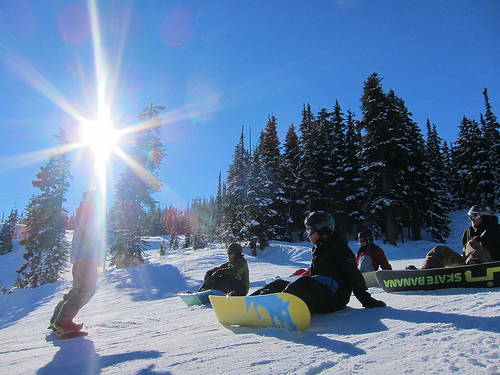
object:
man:
[247, 210, 386, 313]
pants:
[249, 275, 352, 314]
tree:
[357, 70, 421, 247]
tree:
[423, 120, 453, 243]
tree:
[325, 98, 358, 239]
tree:
[205, 165, 223, 240]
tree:
[12, 127, 75, 289]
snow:
[0, 334, 161, 375]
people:
[187, 242, 250, 295]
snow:
[327, 343, 500, 375]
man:
[47, 187, 103, 332]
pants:
[50, 260, 98, 327]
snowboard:
[47, 320, 84, 337]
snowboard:
[208, 293, 311, 332]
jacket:
[70, 201, 102, 264]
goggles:
[303, 224, 335, 241]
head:
[304, 211, 336, 244]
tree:
[467, 86, 500, 213]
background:
[0, 69, 499, 270]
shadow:
[35, 331, 173, 375]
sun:
[79, 117, 121, 157]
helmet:
[82, 189, 96, 202]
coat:
[69, 200, 108, 263]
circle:
[54, 75, 161, 188]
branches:
[239, 111, 290, 255]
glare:
[51, 64, 177, 183]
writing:
[374, 260, 500, 293]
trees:
[146, 203, 177, 247]